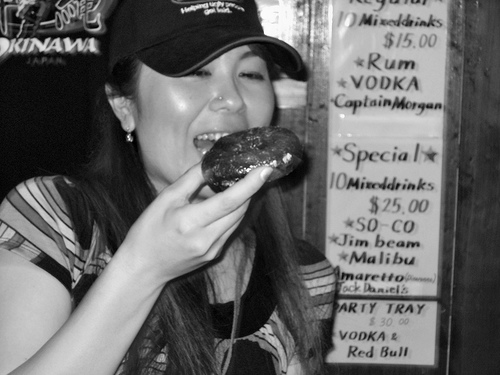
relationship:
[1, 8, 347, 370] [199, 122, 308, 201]
woman eating eating doughnut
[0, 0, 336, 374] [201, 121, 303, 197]
girl holding doughnut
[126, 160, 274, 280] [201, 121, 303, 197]
hand holding doughnut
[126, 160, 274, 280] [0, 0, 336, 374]
hand belonging to girl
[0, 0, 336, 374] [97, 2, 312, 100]
girl wearing baseball cap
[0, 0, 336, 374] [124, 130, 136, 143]
girl wearing earring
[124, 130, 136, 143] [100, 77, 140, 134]
earring worn in ear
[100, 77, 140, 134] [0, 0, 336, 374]
ear belonging to girl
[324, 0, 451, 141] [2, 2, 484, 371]
sign posted on wall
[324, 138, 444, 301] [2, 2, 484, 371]
drink sign posted on wall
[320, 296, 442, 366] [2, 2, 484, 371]
bar sign posted on wall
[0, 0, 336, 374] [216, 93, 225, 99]
girl wearing jewelry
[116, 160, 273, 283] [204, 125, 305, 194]
hand holding doughnut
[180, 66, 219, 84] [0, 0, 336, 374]
left eye belonging to girl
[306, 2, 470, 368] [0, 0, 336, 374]
bar sign posted behind girl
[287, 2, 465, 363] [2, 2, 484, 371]
drink sign posted on wall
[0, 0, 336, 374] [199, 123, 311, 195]
girl holding doughnut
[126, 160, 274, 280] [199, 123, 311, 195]
hand holding doughnut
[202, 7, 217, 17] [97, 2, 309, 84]
word stitched on baseball cap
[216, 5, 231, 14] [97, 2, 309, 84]
word stitched on baseball cap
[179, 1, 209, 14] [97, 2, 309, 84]
word stitched on baseball cap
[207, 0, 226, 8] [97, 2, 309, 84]
word stitched on baseball cap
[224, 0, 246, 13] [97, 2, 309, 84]
word stitched on baseball cap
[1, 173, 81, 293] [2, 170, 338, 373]
shirt sleeve belonging to shirt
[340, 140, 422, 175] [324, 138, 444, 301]
word written on drink sign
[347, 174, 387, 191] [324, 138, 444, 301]
word written on drink sign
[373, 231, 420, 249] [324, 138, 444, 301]
word written on drink sign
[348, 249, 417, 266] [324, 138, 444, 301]
word written on drink sign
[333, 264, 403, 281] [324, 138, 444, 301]
word written on drink sign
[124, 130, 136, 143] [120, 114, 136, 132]
earring hanging in lobe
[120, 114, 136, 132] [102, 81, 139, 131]
lobe belonging to ear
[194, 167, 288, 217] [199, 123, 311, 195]
index finger holding doughnut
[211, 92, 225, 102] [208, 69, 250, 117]
jewelry in nose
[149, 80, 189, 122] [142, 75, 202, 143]
reflection on cheek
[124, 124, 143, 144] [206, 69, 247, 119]
earring in nose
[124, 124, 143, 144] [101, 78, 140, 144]
earring in ear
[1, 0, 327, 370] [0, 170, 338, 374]
girl wearing shirt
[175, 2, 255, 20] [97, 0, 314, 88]
white letters on hat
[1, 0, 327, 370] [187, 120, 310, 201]
girl eating doughnut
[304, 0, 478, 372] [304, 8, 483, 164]
sign on wall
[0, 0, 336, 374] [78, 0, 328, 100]
girl wearing hat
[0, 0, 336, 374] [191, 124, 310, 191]
girl holding doughnut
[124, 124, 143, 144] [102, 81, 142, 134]
earring on ear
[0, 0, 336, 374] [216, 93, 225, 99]
girl has jewelry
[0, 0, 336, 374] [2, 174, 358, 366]
girl wearing shirt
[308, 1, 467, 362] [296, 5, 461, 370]
list of drinks on board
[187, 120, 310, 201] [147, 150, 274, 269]
doughnut in hand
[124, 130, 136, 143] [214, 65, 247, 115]
earring in nose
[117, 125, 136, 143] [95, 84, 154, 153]
earring hangs down hangs down ear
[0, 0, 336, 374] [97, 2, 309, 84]
girl wears baseball cap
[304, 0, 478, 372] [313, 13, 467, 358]
sign on wall